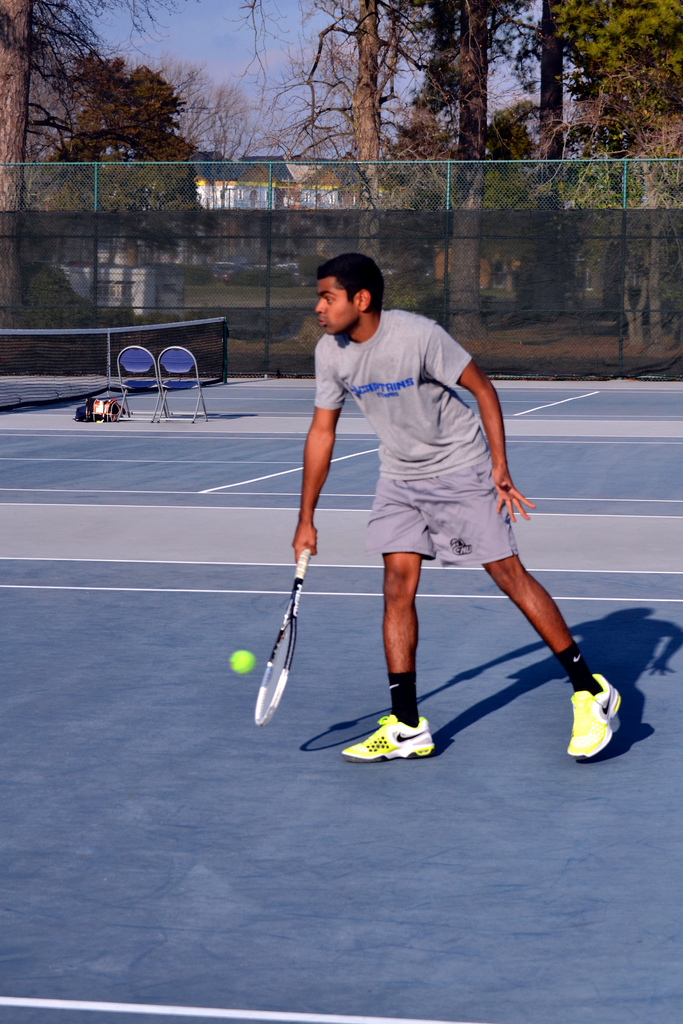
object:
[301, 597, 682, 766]
no object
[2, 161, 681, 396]
fence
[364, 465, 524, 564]
athletic shorts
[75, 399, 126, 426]
tennis bag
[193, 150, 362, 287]
building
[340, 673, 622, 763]
tennis shoes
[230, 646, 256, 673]
tennis ball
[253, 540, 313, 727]
tennis racket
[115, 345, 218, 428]
folding chairs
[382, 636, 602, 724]
socks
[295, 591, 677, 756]
shadow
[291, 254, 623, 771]
tennis player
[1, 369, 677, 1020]
court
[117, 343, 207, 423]
chair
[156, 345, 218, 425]
chair